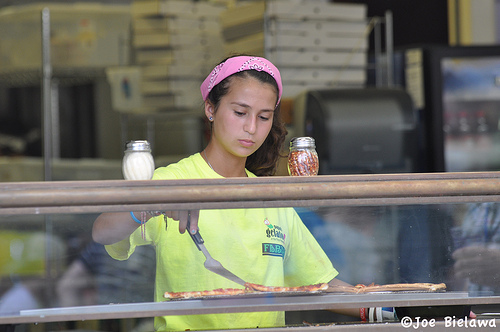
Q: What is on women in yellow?
A: Pink headband.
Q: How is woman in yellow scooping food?
A: Spatula.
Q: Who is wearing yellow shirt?
A: Woman in pink headband.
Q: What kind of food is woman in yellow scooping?
A: Pizza.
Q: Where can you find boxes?
A: Stacked behind woman in yellow.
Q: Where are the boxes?
A: At the background.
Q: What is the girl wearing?
A: A pink hair band.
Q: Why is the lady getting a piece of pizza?
A: She is hungry.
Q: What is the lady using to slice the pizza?
A: A knife.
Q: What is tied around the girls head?
A: A pink kerchief.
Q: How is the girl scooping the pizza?
A: Using a scooper.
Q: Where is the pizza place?
A: In a warming tray.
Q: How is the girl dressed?
A: In a yellow shirt.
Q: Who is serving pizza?
A: A girl.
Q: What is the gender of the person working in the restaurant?
A: Female.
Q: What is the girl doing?
A: Serving food.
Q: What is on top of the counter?
A: Jars.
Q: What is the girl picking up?
A: Pizza.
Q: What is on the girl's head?
A: A pink bandana.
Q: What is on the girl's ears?
A: Earrings.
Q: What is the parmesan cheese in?
A: A glass container.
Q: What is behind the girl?
A: A paper towel holder.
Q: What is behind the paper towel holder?
A: Pizza boxes.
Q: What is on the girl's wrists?
A: Wristbands.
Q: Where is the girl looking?
A: At the slice of pizza.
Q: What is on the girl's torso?
A: A yellow shirt.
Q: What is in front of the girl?
A: A glass sneeze guard.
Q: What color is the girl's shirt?
A: Yellow.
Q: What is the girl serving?
A: Pizza.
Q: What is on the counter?
A: Shakers.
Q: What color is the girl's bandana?
A: Pink.